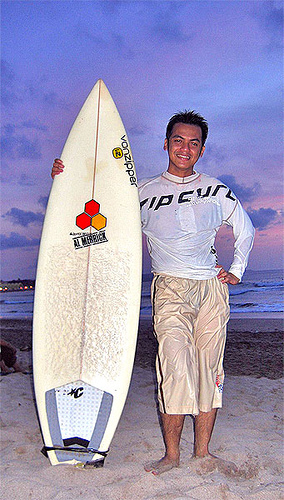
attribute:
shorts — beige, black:
[145, 272, 239, 396]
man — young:
[140, 103, 250, 430]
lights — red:
[2, 283, 34, 292]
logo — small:
[112, 135, 137, 188]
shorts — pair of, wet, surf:
[144, 266, 238, 418]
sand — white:
[51, 466, 113, 491]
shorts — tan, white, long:
[148, 266, 231, 418]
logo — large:
[136, 191, 208, 216]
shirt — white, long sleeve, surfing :
[137, 166, 255, 280]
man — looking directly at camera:
[135, 112, 252, 238]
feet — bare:
[142, 450, 238, 480]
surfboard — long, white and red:
[24, 70, 142, 450]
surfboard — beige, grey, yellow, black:
[25, 68, 151, 431]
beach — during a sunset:
[230, 311, 280, 390]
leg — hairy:
[189, 408, 219, 453]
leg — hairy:
[154, 411, 185, 458]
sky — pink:
[2, 1, 283, 279]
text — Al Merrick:
[70, 229, 108, 249]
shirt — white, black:
[129, 170, 262, 284]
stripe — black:
[147, 273, 165, 412]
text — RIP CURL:
[139, 185, 237, 208]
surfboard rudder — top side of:
[30, 373, 119, 471]